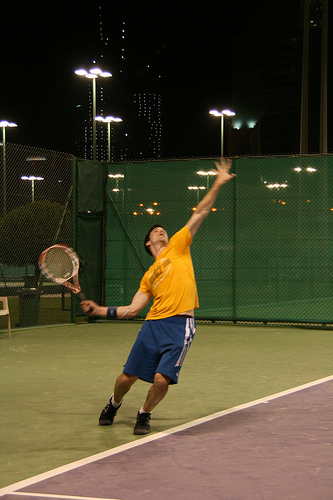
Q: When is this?
A: At night.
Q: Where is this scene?
A: A tennis court.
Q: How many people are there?
A: One.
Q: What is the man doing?
A: Playing tennis.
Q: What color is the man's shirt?
A: Yellow.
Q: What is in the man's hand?
A: A tennis racket.